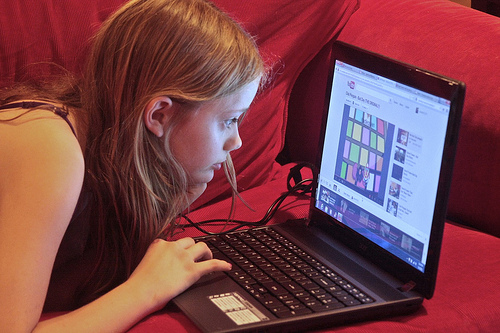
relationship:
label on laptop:
[205, 290, 272, 327] [171, 40, 465, 332]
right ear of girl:
[142, 95, 171, 137] [1, 1, 263, 332]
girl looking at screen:
[1, 1, 263, 332] [312, 57, 453, 274]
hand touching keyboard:
[136, 235, 233, 302] [189, 226, 377, 319]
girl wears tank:
[1, 1, 263, 332] [0, 96, 78, 137]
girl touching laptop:
[1, 1, 263, 332] [171, 40, 465, 332]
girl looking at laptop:
[1, 1, 263, 332] [171, 40, 465, 332]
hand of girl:
[136, 235, 233, 302] [1, 1, 263, 332]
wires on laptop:
[173, 178, 315, 234] [171, 40, 465, 332]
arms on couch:
[0, 121, 131, 332] [1, 0, 500, 331]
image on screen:
[334, 106, 396, 206] [312, 57, 453, 274]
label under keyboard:
[205, 290, 272, 327] [189, 226, 377, 319]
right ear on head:
[142, 95, 171, 137] [98, 0, 259, 185]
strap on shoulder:
[1, 97, 79, 137] [1, 104, 87, 187]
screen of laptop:
[312, 57, 453, 274] [171, 40, 465, 332]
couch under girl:
[1, 0, 500, 331] [1, 1, 263, 332]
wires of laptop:
[173, 178, 315, 234] [171, 40, 465, 332]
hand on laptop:
[136, 235, 233, 302] [171, 40, 465, 332]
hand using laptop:
[136, 235, 233, 302] [171, 40, 465, 332]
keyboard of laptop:
[189, 226, 377, 319] [171, 40, 465, 332]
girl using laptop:
[1, 1, 263, 332] [171, 40, 465, 332]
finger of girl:
[201, 257, 233, 276] [1, 1, 263, 332]